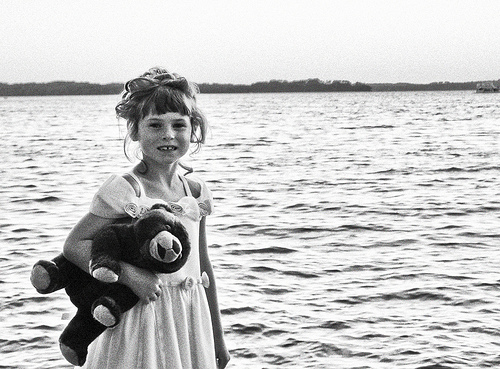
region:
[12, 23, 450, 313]
picture is black and white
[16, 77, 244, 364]
a girl holding a bear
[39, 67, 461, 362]
the girl is next to the water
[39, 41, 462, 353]
picture taken outdoors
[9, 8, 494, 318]
picture taken during the day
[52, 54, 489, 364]
picture taken outside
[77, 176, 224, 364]
the girl is wearing a dress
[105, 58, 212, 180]
hair is up on her head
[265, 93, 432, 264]
the water has small waves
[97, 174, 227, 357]
the girl holds bear around its neck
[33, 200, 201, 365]
A large teddy bear.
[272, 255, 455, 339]
Ripples on the water.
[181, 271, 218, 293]
A very small bow.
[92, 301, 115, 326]
The front paw of the stuffed bear.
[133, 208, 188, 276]
The face of the stuffed bear.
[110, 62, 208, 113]
A very fancy hair style.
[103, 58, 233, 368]
A girl standing in shallow water.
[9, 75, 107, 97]
Trees on the shore in the distance.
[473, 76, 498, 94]
A small boat in the background.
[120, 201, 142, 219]
A rose design on the dress.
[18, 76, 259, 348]
girl holding a stuffed animal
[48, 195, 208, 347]
teddy bear in right arm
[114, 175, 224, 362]
girl wearing a light colored dress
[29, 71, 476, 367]
girl standing by the water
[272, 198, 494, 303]
ripples are in the water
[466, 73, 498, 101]
a dock is in the background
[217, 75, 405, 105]
trees behind the water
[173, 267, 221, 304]
bows on the front of dress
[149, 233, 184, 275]
bears nose is white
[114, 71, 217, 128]
girl's hair is put up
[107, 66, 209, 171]
The girls hair is brown.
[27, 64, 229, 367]
The girl is holding a teddy bear.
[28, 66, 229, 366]
The girl is wearing a dress.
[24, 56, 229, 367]
The girl is wearing a white dress.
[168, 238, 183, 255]
The tedddy bears nose is black.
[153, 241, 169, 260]
The teddy bears mouth is black.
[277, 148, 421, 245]
The water in the background is dark in color.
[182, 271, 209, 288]
The girls dress has a bow.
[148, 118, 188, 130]
The girls eyes are brown.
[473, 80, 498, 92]
The object in the background is dark in color.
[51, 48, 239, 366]
little girl and teddy bear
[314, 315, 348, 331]
ripple in the water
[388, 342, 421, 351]
ripple in the water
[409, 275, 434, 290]
ripple in the water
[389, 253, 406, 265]
ripple in the water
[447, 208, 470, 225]
ripple in the water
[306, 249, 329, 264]
ripple in the water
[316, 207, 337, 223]
ripple in the water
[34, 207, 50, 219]
ripple in the water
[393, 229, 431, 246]
ripple in the water